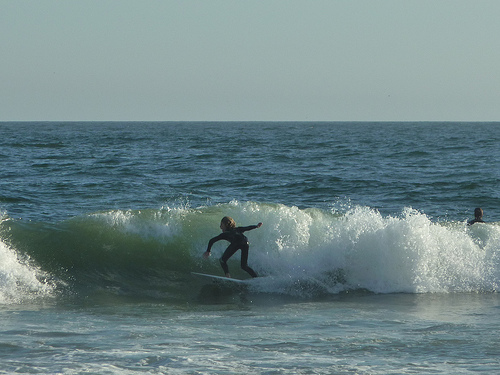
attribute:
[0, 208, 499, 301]
wave — nice, large, huge, great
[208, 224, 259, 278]
wetsuit — black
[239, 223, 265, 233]
arm — out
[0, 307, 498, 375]
water — calm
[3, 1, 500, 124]
sky — gray, gloomy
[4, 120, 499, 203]
water — empty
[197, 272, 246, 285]
surfboard — white